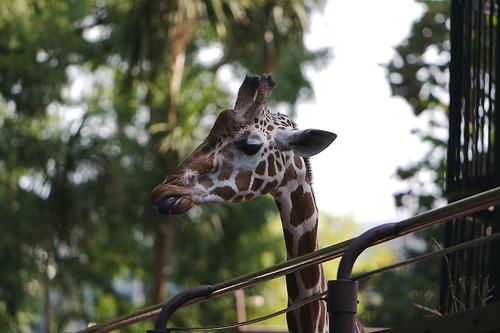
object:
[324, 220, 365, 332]
pole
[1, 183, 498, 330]
fene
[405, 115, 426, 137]
ground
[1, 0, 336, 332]
trees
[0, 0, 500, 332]
photograph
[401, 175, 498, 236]
rail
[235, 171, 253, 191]
brown spot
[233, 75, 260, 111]
horns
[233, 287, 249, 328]
wood piece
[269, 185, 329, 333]
giraffe neck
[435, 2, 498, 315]
cage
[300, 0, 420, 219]
clear sky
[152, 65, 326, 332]
animal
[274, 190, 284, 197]
spots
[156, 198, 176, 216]
black tongue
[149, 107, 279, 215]
face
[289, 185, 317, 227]
brown spots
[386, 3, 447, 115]
leaves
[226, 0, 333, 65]
leaves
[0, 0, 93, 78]
leaves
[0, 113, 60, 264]
leaves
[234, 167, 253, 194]
spots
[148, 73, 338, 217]
head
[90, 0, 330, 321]
palm tree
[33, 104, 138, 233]
leaf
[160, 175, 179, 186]
nose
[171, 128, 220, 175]
strip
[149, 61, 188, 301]
stem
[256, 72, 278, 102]
horn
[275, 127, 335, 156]
ear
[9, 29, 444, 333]
zoo